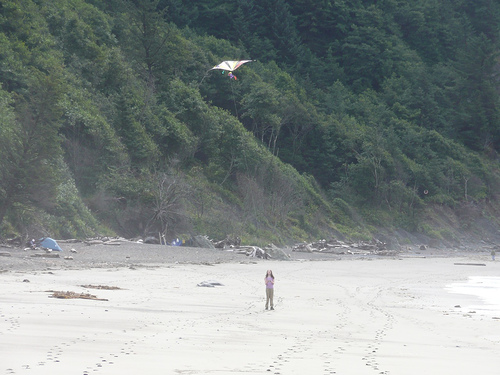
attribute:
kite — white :
[211, 57, 251, 81]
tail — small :
[227, 69, 239, 82]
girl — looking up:
[258, 257, 283, 319]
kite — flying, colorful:
[198, 46, 267, 104]